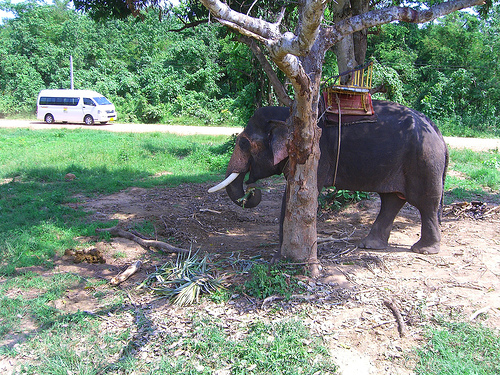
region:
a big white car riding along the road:
[28, 87, 135, 144]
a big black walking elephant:
[202, 70, 460, 255]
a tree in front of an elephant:
[232, 2, 370, 274]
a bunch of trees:
[35, 7, 201, 89]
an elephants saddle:
[322, 71, 389, 132]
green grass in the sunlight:
[5, 130, 130, 185]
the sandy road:
[105, 119, 246, 133]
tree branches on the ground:
[127, 237, 236, 316]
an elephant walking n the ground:
[225, 96, 439, 258]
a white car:
[32, 81, 119, 126]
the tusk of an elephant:
[204, 167, 239, 196]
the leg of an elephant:
[401, 190, 451, 257]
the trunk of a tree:
[259, 1, 343, 270]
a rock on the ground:
[101, 247, 153, 289]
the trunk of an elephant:
[221, 170, 266, 209]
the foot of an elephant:
[402, 232, 444, 258]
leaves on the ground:
[137, 243, 222, 310]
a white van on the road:
[31, 85, 123, 128]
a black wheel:
[78, 112, 99, 129]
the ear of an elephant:
[265, 115, 297, 169]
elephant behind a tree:
[202, 74, 464, 273]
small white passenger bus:
[25, 83, 126, 132]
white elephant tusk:
[178, 159, 248, 208]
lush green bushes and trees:
[145, 42, 212, 114]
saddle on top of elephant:
[305, 52, 401, 139]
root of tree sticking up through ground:
[86, 206, 206, 264]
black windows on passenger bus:
[35, 90, 85, 110]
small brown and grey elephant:
[195, 80, 460, 260]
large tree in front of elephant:
[142, 0, 454, 292]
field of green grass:
[39, 133, 110, 175]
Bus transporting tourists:
[31, 86, 117, 126]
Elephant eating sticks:
[196, 95, 456, 255]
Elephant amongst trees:
[221, 5, 361, 255]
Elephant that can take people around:
[210, 55, 445, 265]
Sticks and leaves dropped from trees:
[86, 220, 271, 325]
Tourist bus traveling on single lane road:
[20, 80, 245, 140]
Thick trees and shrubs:
[115, 20, 245, 120]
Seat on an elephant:
[310, 61, 415, 146]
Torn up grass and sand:
[215, 275, 462, 370]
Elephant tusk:
[205, 150, 260, 215]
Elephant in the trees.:
[203, 92, 460, 252]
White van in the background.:
[37, 85, 114, 125]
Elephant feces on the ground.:
[57, 245, 108, 274]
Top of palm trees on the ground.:
[139, 249, 246, 305]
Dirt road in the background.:
[0, 111, 497, 161]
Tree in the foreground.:
[71, 0, 486, 275]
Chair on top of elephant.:
[318, 61, 380, 116]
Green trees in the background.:
[4, 7, 496, 142]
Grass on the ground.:
[2, 127, 498, 371]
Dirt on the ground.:
[106, 174, 488, 333]